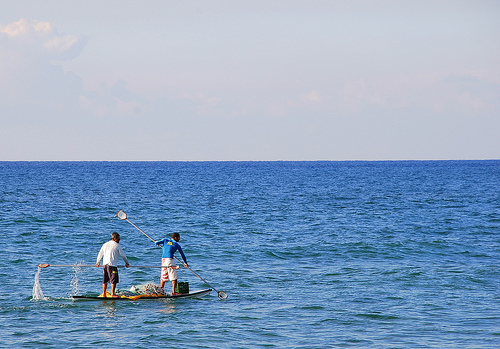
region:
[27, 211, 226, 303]
people are paddle boarding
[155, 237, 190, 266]
the man wears a blue shirt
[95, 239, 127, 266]
the man wears a white shirt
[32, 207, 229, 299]
the men have paddles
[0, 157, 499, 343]
the men are in the ocean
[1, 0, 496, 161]
it is cloudy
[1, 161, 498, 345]
the water is blue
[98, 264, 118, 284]
the man has black shorts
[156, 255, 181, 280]
the man has patterned shorts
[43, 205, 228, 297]
the paddles are long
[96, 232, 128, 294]
skinny male paddling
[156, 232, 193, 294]
skinny male paddling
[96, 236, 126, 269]
long sleeved white shirt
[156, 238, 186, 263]
long sleeved blue and yellow shirt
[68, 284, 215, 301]
very long and wide surfboard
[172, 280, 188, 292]
black box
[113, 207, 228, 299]
long white ore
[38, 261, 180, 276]
long white ore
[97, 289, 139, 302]
yellow piece of fabric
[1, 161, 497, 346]
still blue vast of ocean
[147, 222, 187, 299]
man wearing blue shirt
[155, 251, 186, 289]
white swim trunks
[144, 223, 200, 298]
man fishing with net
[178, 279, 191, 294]
bucket for fish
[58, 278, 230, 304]
small fishing canoe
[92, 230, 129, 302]
man wearing blue shorts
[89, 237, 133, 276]
white long sleeve shirt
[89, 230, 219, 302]
two man fishing in the ocean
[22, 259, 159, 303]
long fishing net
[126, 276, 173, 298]
lots of fish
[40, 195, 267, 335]
Two people out on the open ocean.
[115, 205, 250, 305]
The man is holding a long pole.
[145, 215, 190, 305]
The man has a blue shirt on.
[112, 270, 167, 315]
A pile of fishing nets.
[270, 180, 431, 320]
The ocean is calm.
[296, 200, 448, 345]
The water is a bluish-green.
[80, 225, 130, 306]
The man is wearing black shorts.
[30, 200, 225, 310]
The men are on top of a paddleboard.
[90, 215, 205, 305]
The men are barefoot.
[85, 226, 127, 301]
The man is wearing a white shirt.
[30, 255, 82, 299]
they are splashing water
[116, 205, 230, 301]
the man in the front has a paddle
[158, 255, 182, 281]
the man in the front is wearing white shorts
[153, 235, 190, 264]
the man in the front is wearing a blue shirt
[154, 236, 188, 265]
the man in the front is wearing a long sleeved shirt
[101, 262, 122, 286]
the man in the front is wearing black shorts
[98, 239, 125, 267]
the man in the back is wearing a white shirt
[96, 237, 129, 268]
the man in the back is wearing a long sleeved shirt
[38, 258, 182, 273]
the man in the back is holding a paddle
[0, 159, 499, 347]
the ocean is very blue